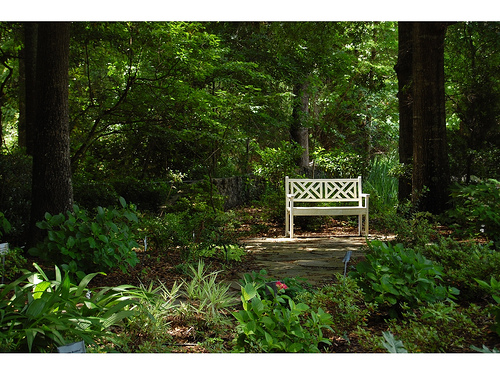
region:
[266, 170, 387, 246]
the bench is in the woods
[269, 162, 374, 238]
the bench is white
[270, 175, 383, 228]
the bench is wooden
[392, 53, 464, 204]
the tree trunk is big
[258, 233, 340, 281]
the shadows fro the trees are on the ground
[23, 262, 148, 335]
the leaves are long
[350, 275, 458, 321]
the leaves are green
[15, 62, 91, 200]
the tree trunk is brown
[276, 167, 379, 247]
the bench is empty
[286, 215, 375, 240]
the bench has legs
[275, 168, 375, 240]
white wooden park bench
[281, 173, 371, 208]
lattice style back on bench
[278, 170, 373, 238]
bench sitting among trees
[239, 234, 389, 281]
shadow of trees cast onto ground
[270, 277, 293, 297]
pink flower bloom in low bush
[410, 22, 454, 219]
narrow tree trunk on right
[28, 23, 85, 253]
narrow tree trunk on left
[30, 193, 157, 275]
low bush at bottom of tree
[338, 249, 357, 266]
blue flower in low bushes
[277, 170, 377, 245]
park bench in a sunny spot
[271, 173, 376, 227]
a bench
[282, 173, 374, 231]
the bench is white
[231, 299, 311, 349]
the leaves are green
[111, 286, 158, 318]
the plants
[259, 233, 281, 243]
light on the ground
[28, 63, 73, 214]
a tree trunk that is brown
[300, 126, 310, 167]
a tree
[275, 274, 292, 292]
a red flower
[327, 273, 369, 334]
small weeds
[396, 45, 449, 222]
a brown tree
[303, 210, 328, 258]
part of a bench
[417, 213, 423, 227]
edge of a stem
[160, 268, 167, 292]
part of a bush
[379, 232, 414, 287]
edge of a bush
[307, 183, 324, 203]
edge of a bench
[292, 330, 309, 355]
part of a tree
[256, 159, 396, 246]
sitting bench between the forest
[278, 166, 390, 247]
sandle color wooden bench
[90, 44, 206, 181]
trees with branches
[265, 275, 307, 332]
red color flower with plant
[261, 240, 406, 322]
dirt with plants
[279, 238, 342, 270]
shadows of the tree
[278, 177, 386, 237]
sandle color sitting bench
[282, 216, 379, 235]
stand of the sitting bench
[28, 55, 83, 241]
big tree in the forest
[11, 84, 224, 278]
dry leaves with the plants and trees